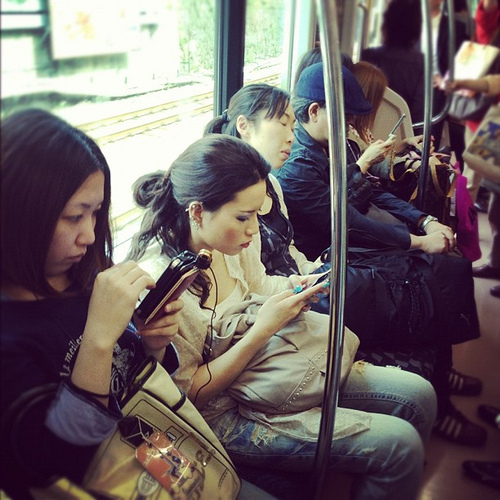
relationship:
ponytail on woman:
[138, 145, 193, 246] [159, 112, 283, 496]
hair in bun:
[8, 115, 77, 276] [126, 178, 167, 206]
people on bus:
[23, 26, 457, 441] [48, 27, 500, 498]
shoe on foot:
[439, 362, 494, 405] [424, 370, 494, 404]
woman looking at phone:
[0, 111, 277, 499] [130, 249, 200, 324]